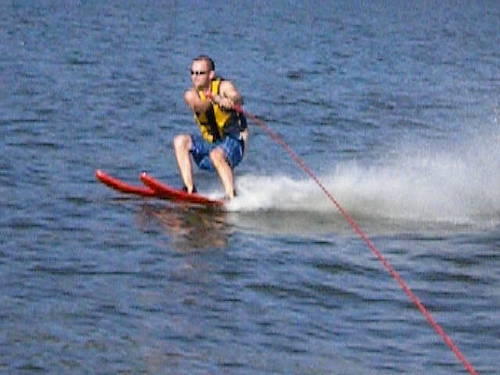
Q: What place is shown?
A: It is a lake.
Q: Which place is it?
A: It is a lake.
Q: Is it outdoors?
A: Yes, it is outdoors.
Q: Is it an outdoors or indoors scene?
A: It is outdoors.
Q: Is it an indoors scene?
A: No, it is outdoors.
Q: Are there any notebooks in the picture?
A: No, there are no notebooks.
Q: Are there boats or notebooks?
A: No, there are no notebooks or boats.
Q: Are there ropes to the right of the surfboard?
A: Yes, there is a rope to the right of the surfboard.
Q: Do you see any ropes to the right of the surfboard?
A: Yes, there is a rope to the right of the surfboard.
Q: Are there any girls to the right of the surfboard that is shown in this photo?
A: No, there is a rope to the right of the surfboard.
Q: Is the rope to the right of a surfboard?
A: Yes, the rope is to the right of a surfboard.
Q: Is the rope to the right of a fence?
A: No, the rope is to the right of a surfboard.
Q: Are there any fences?
A: No, there are no fences.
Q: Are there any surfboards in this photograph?
A: Yes, there is a surfboard.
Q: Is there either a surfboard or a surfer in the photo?
A: Yes, there is a surfboard.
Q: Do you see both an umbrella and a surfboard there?
A: No, there is a surfboard but no umbrellas.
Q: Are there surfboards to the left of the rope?
A: Yes, there is a surfboard to the left of the rope.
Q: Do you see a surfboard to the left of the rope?
A: Yes, there is a surfboard to the left of the rope.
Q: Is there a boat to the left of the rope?
A: No, there is a surfboard to the left of the rope.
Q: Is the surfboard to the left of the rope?
A: Yes, the surfboard is to the left of the rope.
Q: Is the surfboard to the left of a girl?
A: No, the surfboard is to the left of the rope.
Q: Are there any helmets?
A: No, there are no helmets.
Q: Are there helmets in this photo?
A: No, there are no helmets.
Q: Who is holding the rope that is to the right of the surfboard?
A: The man is holding the rope.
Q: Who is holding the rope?
A: The man is holding the rope.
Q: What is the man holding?
A: The man is holding the rope.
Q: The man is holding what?
A: The man is holding the rope.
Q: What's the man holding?
A: The man is holding the rope.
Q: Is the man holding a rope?
A: Yes, the man is holding a rope.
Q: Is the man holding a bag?
A: No, the man is holding a rope.